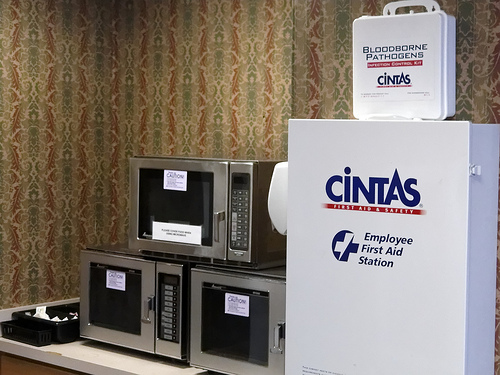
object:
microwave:
[71, 241, 189, 365]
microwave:
[126, 152, 287, 270]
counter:
[0, 297, 207, 374]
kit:
[343, 5, 466, 122]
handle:
[210, 208, 227, 245]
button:
[233, 252, 246, 259]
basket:
[0, 298, 80, 349]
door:
[136, 166, 215, 249]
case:
[258, 115, 500, 374]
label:
[160, 166, 190, 193]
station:
[465, 159, 488, 181]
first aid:
[349, 25, 458, 123]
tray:
[3, 298, 77, 352]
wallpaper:
[0, 0, 120, 247]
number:
[232, 241, 236, 246]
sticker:
[145, 214, 208, 250]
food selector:
[152, 271, 179, 344]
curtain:
[0, 0, 287, 154]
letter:
[322, 165, 421, 208]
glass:
[138, 167, 213, 247]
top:
[41, 350, 139, 375]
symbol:
[322, 223, 358, 267]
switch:
[227, 183, 252, 248]